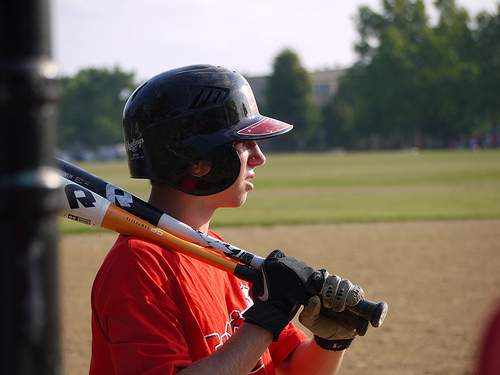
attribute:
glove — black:
[243, 251, 323, 341]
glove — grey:
[304, 266, 359, 341]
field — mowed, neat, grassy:
[57, 147, 499, 224]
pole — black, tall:
[0, 0, 51, 375]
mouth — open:
[242, 175, 260, 189]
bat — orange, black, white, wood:
[57, 174, 369, 336]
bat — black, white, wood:
[52, 152, 389, 327]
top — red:
[88, 252, 199, 372]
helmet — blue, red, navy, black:
[112, 62, 296, 196]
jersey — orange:
[98, 235, 241, 360]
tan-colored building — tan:
[301, 62, 358, 112]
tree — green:
[56, 64, 138, 147]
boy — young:
[88, 62, 363, 373]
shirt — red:
[78, 225, 314, 374]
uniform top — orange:
[88, 223, 313, 373]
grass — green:
[268, 162, 495, 212]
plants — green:
[41, 0, 498, 235]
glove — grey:
[305, 263, 374, 355]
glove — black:
[242, 244, 319, 326]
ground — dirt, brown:
[60, 216, 499, 373]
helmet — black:
[109, 53, 301, 193]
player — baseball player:
[82, 62, 366, 373]